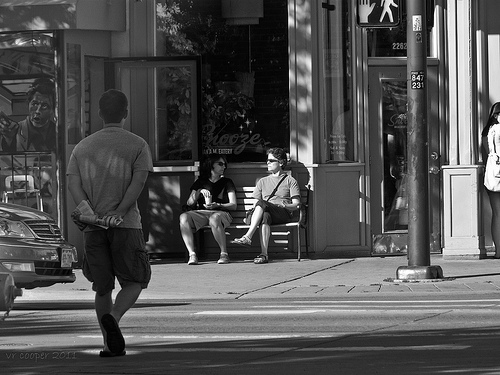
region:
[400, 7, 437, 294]
metal lamp post on sidewalk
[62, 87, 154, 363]
person walking in street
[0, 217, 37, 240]
head light on car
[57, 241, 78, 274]
front license plate on car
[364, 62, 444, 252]
door on front of building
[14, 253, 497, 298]
sidewalk with lamp post in middle of it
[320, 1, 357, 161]
window beside entrance door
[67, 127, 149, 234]
person wearing short sleeve shirt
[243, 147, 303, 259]
person sitting on bench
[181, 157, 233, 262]
person sitting on bench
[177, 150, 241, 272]
Woman sitting on bench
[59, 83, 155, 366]
Man crossing city street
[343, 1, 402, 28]
Pedestrian walk control signal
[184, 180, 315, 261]
Wooden bench on sidewalk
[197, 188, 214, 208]
Beverage in woman's hands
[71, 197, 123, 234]
Newspaper in man's hands behind back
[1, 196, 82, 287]
Front edge of car waiting for pedestrian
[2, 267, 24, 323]
Fire hydrant nozzle cover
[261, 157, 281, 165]
Sunglasses on woman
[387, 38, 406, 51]
Building address painted on window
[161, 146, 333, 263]
two people sitting on the bench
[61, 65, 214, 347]
a man crossing the street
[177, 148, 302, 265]
Two people sit together.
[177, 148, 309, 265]
The people sit on a bench.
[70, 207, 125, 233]
The man's hands are behind his back.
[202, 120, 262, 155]
A name is on the window.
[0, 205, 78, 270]
A car is on the street.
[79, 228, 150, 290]
The man wears shorts.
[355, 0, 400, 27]
A walk sign is on the pole.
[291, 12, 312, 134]
Sunlight is on the building.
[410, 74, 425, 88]
Numbers are on the pole.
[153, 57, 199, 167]
The building window is open.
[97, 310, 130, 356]
a man's shoe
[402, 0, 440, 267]
a tall black pole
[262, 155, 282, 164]
dark black sunglasses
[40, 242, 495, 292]
part of a concrete sidewalk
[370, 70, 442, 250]
the door of a building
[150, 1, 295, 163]
a large window of a building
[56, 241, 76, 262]
a car tag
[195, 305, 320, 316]
a long white line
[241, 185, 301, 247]
part of a bench